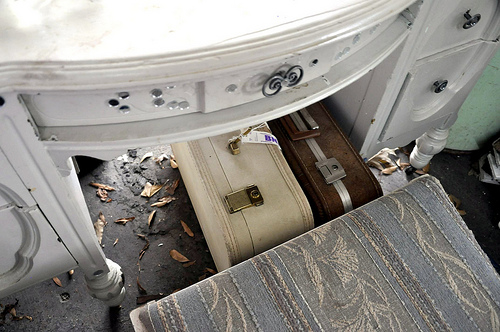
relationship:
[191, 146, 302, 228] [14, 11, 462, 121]
suitcase under vanity table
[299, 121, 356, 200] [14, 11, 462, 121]
suitcase under vanity table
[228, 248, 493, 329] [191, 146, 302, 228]
bench in front of suitcase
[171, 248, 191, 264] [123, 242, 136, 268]
leaf scattered on floor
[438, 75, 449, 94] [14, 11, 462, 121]
drawer pull attached to vanity table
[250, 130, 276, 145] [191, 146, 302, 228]
tag attached to suitcase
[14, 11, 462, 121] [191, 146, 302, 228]
vanity table above suitcase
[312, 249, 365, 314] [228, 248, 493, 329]
pattern stitched on bench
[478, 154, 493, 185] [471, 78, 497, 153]
block piled against wall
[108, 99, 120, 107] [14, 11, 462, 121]
dot attached to vanity table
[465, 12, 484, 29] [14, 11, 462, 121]
drawer pull attached to vanity table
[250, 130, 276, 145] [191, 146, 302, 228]
tag on suitcase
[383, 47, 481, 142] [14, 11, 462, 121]
drawer in vanity table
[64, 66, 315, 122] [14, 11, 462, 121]
drawer in vanity table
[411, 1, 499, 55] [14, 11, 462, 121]
drawer in vanity table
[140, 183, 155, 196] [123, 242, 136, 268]
leaf lying on floor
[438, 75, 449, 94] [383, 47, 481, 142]
drawer pull attached to drawer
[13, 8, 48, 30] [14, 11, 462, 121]
light shining on vanity table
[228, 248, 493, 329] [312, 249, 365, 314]
bench has pattern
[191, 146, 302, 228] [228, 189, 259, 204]
suitcase has latch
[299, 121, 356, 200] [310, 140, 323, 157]
suitcase has band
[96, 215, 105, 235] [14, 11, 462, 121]
leaf under vanity table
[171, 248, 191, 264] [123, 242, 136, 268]
leaf lying on floor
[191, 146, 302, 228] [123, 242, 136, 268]
suitcase sitting on floor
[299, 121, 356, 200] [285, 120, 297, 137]
suitcase has handle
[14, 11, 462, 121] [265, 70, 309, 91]
vanity table has drawer pull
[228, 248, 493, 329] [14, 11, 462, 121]
bench next to vanity table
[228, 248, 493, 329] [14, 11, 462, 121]
bench in front of vanity table